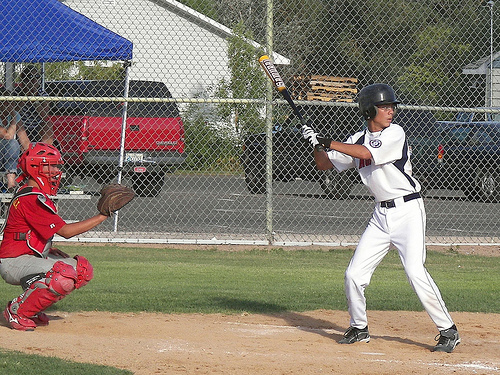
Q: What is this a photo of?
A: Baseball game.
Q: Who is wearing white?
A: The batter.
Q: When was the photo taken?
A: Daytime.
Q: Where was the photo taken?
A: Baseball park.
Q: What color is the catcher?
A: Red.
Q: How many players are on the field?
A: Two.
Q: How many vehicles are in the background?
A: Three.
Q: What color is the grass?
A: Green.